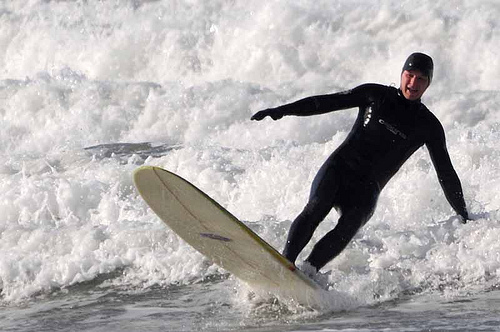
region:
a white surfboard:
[131, 162, 318, 302]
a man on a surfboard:
[133, 50, 470, 307]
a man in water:
[250, 51, 471, 277]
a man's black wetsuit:
[251, 82, 469, 274]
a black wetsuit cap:
[403, 52, 435, 79]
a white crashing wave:
[3, 72, 498, 164]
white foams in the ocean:
[0, 1, 499, 298]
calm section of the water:
[0, 285, 497, 330]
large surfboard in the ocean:
[133, 167, 324, 310]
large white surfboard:
[135, 167, 325, 313]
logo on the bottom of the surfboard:
[198, 231, 231, 244]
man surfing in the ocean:
[249, 52, 473, 267]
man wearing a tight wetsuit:
[246, 53, 470, 270]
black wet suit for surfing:
[248, 82, 470, 267]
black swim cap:
[400, 51, 432, 78]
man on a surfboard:
[249, 53, 472, 273]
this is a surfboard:
[111, 148, 339, 315]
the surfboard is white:
[125, 134, 349, 328]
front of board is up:
[122, 142, 343, 310]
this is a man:
[232, 17, 486, 296]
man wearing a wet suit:
[250, 51, 474, 278]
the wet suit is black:
[228, 3, 493, 295]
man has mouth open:
[400, 76, 426, 100]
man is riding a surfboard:
[102, 22, 493, 322]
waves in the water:
[23, 12, 498, 316]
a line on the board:
[126, 146, 306, 319]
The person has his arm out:
[219, 46, 354, 134]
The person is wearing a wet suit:
[231, 18, 482, 278]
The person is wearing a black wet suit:
[233, 12, 483, 287]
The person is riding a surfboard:
[111, 8, 483, 304]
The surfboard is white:
[126, 150, 268, 312]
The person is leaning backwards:
[231, 10, 481, 276]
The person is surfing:
[103, 23, 480, 309]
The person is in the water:
[228, 0, 498, 226]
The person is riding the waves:
[224, 17, 485, 298]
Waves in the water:
[21, 20, 217, 153]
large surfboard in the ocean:
[132, 165, 323, 302]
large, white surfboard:
[135, 168, 323, 302]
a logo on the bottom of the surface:
[198, 229, 234, 243]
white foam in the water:
[0, 0, 497, 284]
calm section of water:
[3, 277, 495, 330]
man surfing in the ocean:
[248, 45, 473, 275]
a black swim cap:
[402, 51, 433, 73]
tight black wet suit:
[252, 83, 469, 268]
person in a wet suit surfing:
[252, 54, 472, 274]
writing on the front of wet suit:
[375, 118, 408, 142]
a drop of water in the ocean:
[146, 270, 151, 274]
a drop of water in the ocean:
[380, 260, 385, 267]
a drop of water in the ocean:
[404, 292, 415, 299]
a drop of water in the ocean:
[358, 275, 368, 287]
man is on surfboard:
[134, 47, 471, 299]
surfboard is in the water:
[132, 164, 336, 301]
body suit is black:
[284, 47, 464, 261]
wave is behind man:
[1, 0, 496, 298]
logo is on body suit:
[378, 115, 408, 140]